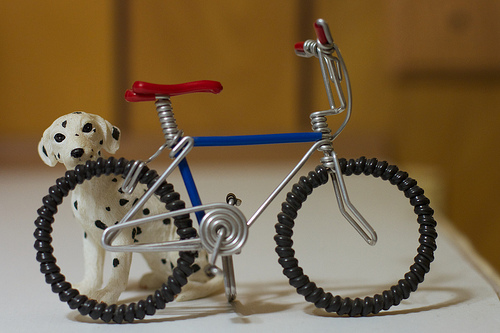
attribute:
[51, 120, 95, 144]
eyes — black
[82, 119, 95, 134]
eye — black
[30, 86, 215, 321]
dalmation — dog, plastic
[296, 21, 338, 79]
bars — silver, red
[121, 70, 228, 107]
seat — red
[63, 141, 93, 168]
nose — bag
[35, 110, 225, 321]
dog — black, white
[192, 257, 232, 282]
pedal — silver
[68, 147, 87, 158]
nose — black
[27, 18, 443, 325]
bicycle — replica, miniature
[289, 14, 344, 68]
handle bars — red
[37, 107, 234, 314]
toy dog — black and white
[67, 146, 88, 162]
dog nose — black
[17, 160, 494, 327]
table — white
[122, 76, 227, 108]
seat — red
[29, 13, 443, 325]
bike frame — blue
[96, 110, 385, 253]
frame — blue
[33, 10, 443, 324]
bike — miniature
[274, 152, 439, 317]
tire — black, phone cord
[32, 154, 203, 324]
tire — black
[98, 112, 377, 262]
frame — blue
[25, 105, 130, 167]
face — spotted